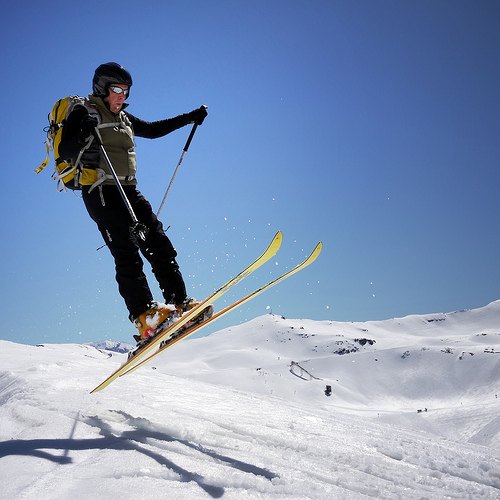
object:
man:
[58, 61, 213, 334]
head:
[94, 62, 133, 113]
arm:
[130, 114, 188, 139]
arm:
[58, 111, 80, 159]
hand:
[189, 106, 208, 126]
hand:
[79, 116, 100, 135]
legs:
[94, 195, 156, 314]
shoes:
[133, 300, 181, 339]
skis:
[88, 232, 281, 396]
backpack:
[37, 95, 102, 190]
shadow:
[0, 409, 278, 497]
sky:
[0, 0, 500, 349]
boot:
[133, 303, 180, 343]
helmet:
[91, 61, 134, 99]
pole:
[153, 105, 208, 217]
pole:
[93, 126, 146, 243]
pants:
[82, 184, 188, 323]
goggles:
[107, 85, 132, 95]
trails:
[365, 445, 499, 491]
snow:
[0, 298, 500, 499]